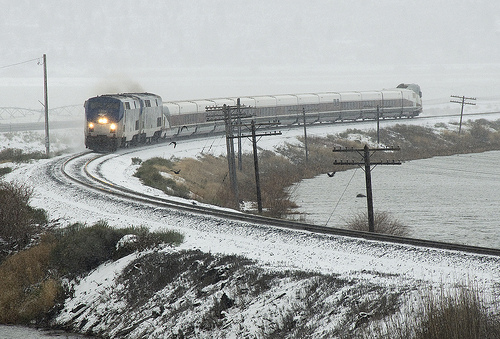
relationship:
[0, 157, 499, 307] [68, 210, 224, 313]
snow on ground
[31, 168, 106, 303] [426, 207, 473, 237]
ground covered with snow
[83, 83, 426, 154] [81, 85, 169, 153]
train on train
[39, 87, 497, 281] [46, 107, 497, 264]
train on tracks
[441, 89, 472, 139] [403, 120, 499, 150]
pole on embankment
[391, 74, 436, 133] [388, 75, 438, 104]
caboose has spoiler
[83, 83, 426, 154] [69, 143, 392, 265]
train on tracks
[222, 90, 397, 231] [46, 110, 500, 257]
power lines are along tracks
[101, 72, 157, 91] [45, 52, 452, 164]
smoke comes from train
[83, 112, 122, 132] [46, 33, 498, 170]
lights on train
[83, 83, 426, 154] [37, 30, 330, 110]
train in fog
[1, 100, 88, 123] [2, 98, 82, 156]
sprinkler in field